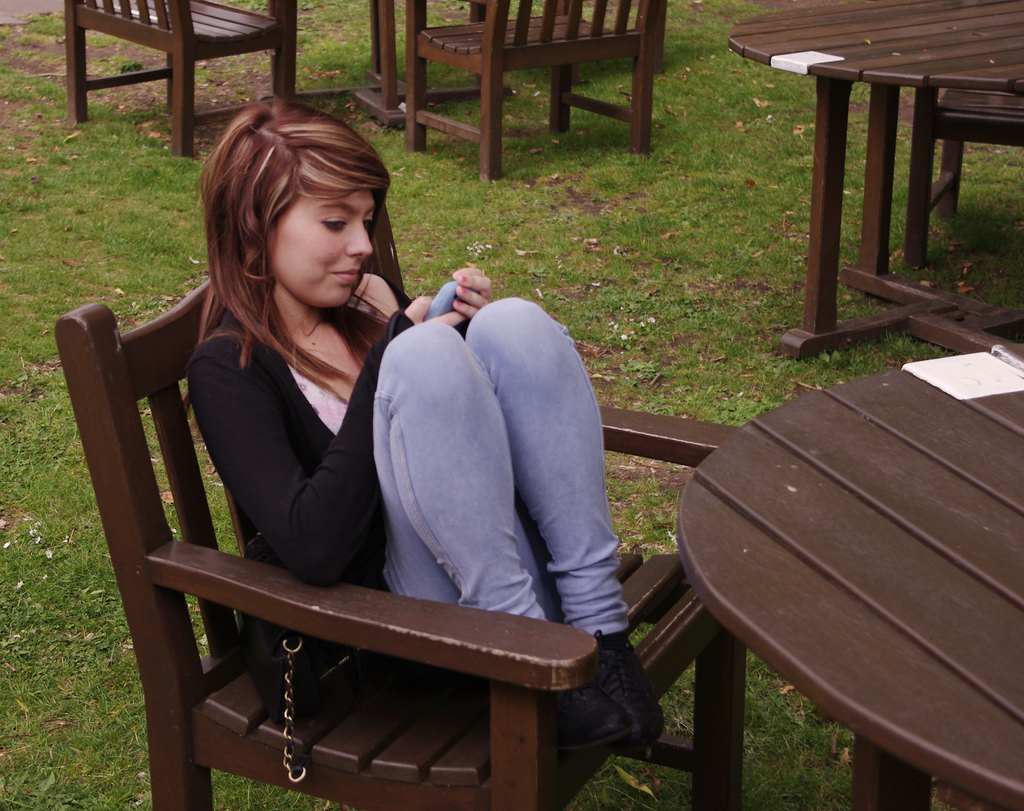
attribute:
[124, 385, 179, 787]
chair — WOODEN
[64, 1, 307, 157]
chair — wooden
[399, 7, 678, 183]
chair — wooden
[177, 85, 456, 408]
hair — brown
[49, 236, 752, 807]
chair — wooden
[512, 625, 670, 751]
shoe — black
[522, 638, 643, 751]
shoe — black, small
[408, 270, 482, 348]
phone — blue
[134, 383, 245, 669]
panel — wooden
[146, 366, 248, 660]
panel — wooden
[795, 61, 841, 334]
panel — wooden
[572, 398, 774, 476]
panel — wooden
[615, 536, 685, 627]
panel — wooden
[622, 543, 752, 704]
panel — wooden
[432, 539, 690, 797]
panel — wooden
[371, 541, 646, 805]
panel — wooden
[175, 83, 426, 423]
hair — brown